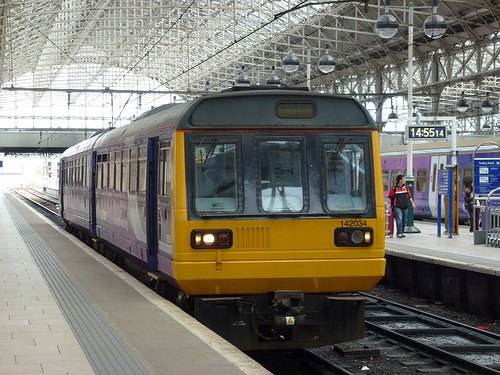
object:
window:
[187, 134, 246, 220]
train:
[57, 83, 389, 353]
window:
[253, 135, 310, 218]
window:
[316, 135, 373, 218]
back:
[58, 148, 67, 219]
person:
[386, 174, 417, 238]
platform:
[385, 211, 500, 277]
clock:
[404, 125, 450, 140]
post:
[407, 115, 460, 236]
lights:
[332, 225, 374, 247]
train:
[378, 143, 500, 227]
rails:
[1, 86, 224, 95]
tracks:
[11, 179, 500, 375]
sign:
[471, 157, 500, 196]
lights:
[423, 13, 448, 40]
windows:
[100, 152, 110, 191]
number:
[340, 220, 344, 227]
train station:
[0, 0, 499, 374]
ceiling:
[0, 2, 500, 100]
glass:
[375, 27, 399, 38]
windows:
[156, 132, 174, 200]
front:
[169, 85, 389, 356]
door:
[146, 135, 160, 279]